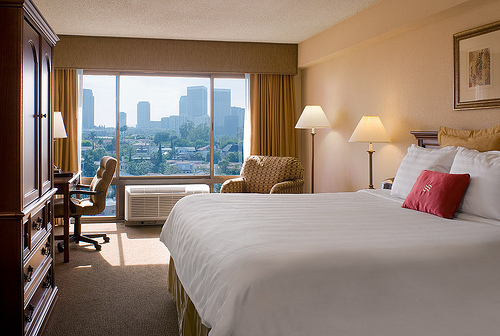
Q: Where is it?
A: This is at the hotel room.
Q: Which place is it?
A: It is a hotel room.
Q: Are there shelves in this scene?
A: No, there are no shelves.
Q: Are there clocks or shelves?
A: No, there are no shelves or clocks.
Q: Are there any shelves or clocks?
A: No, there are no shelves or clocks.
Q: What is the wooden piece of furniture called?
A: The piece of furniture is a dresser.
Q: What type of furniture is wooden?
A: The furniture is a dresser.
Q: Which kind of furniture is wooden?
A: The furniture is a dresser.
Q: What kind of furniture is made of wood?
A: The furniture is a dresser.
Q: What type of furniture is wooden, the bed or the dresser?
A: The dresser is wooden.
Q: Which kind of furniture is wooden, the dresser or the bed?
A: The dresser is wooden.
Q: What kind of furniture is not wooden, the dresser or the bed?
A: The bed is not wooden.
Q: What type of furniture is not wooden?
A: The furniture is a bed.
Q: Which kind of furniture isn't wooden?
A: The furniture is a bed.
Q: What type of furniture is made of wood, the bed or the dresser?
A: The dresser is made of wood.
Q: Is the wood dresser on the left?
A: Yes, the dresser is on the left of the image.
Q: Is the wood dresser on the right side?
A: No, the dresser is on the left of the image.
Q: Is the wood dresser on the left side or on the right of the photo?
A: The dresser is on the left of the image.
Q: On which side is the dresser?
A: The dresser is on the left of the image.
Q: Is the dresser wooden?
A: Yes, the dresser is wooden.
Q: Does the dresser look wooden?
A: Yes, the dresser is wooden.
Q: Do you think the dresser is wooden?
A: Yes, the dresser is wooden.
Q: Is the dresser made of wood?
A: Yes, the dresser is made of wood.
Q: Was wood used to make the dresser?
A: Yes, the dresser is made of wood.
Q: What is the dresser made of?
A: The dresser is made of wood.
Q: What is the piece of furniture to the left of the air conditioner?
A: The piece of furniture is a dresser.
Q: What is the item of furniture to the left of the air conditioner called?
A: The piece of furniture is a dresser.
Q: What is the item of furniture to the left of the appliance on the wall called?
A: The piece of furniture is a dresser.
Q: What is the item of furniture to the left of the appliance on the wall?
A: The piece of furniture is a dresser.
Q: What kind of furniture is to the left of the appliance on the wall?
A: The piece of furniture is a dresser.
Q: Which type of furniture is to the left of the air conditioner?
A: The piece of furniture is a dresser.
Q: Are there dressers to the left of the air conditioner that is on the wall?
A: Yes, there is a dresser to the left of the air conditioner.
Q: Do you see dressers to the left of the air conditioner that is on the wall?
A: Yes, there is a dresser to the left of the air conditioner.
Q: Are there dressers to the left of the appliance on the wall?
A: Yes, there is a dresser to the left of the air conditioner.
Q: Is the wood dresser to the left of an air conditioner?
A: Yes, the dresser is to the left of an air conditioner.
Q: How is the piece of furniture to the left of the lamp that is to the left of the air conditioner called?
A: The piece of furniture is a dresser.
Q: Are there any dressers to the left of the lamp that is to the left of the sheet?
A: Yes, there is a dresser to the left of the lamp.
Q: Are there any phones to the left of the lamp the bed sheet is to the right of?
A: No, there is a dresser to the left of the lamp.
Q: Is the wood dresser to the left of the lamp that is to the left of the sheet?
A: Yes, the dresser is to the left of the lamp.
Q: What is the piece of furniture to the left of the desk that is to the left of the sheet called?
A: The piece of furniture is a dresser.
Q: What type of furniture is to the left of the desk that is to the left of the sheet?
A: The piece of furniture is a dresser.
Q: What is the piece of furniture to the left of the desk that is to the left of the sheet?
A: The piece of furniture is a dresser.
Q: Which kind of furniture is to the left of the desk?
A: The piece of furniture is a dresser.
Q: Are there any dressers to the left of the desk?
A: Yes, there is a dresser to the left of the desk.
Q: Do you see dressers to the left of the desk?
A: Yes, there is a dresser to the left of the desk.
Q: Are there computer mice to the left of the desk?
A: No, there is a dresser to the left of the desk.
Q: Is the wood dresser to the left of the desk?
A: Yes, the dresser is to the left of the desk.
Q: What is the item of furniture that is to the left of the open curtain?
A: The piece of furniture is a dresser.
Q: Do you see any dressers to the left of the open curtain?
A: Yes, there is a dresser to the left of the curtain.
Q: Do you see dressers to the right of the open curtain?
A: No, the dresser is to the left of the curtain.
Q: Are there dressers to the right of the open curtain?
A: No, the dresser is to the left of the curtain.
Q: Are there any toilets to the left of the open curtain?
A: No, there is a dresser to the left of the curtain.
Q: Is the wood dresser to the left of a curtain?
A: Yes, the dresser is to the left of a curtain.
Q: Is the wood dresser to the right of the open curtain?
A: No, the dresser is to the left of the curtain.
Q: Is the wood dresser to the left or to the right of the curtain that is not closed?
A: The dresser is to the left of the curtain.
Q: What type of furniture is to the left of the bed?
A: The piece of furniture is a dresser.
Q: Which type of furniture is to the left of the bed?
A: The piece of furniture is a dresser.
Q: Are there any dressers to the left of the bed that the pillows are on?
A: Yes, there is a dresser to the left of the bed.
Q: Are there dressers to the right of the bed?
A: No, the dresser is to the left of the bed.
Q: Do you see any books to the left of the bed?
A: No, there is a dresser to the left of the bed.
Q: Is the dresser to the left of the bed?
A: Yes, the dresser is to the left of the bed.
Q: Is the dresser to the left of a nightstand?
A: No, the dresser is to the left of the bed.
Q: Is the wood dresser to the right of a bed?
A: No, the dresser is to the left of a bed.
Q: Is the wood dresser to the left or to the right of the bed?
A: The dresser is to the left of the bed.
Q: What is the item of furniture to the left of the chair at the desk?
A: The piece of furniture is a dresser.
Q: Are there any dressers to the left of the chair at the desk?
A: Yes, there is a dresser to the left of the chair.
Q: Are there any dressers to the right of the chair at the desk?
A: No, the dresser is to the left of the chair.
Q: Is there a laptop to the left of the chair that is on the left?
A: No, there is a dresser to the left of the chair.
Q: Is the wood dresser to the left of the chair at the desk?
A: Yes, the dresser is to the left of the chair.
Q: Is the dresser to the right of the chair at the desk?
A: No, the dresser is to the left of the chair.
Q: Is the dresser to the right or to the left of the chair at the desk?
A: The dresser is to the left of the chair.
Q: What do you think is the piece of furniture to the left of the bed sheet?
A: The piece of furniture is a dresser.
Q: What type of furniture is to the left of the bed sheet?
A: The piece of furniture is a dresser.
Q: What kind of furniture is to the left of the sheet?
A: The piece of furniture is a dresser.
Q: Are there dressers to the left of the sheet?
A: Yes, there is a dresser to the left of the sheet.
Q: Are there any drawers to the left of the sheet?
A: No, there is a dresser to the left of the sheet.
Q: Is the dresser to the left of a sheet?
A: Yes, the dresser is to the left of a sheet.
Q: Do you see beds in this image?
A: Yes, there is a bed.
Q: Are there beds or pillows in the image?
A: Yes, there is a bed.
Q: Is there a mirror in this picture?
A: No, there are no mirrors.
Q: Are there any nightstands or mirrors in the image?
A: No, there are no mirrors or nightstands.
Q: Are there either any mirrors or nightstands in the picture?
A: No, there are no mirrors or nightstands.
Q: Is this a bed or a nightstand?
A: This is a bed.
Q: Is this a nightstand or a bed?
A: This is a bed.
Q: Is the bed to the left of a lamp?
A: No, the bed is to the right of a lamp.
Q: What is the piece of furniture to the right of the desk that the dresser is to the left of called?
A: The piece of furniture is a bed.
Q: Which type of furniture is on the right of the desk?
A: The piece of furniture is a bed.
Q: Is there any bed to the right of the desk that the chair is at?
A: Yes, there is a bed to the right of the desk.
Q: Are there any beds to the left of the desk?
A: No, the bed is to the right of the desk.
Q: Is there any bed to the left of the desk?
A: No, the bed is to the right of the desk.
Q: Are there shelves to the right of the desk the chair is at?
A: No, there is a bed to the right of the desk.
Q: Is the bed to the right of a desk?
A: Yes, the bed is to the right of a desk.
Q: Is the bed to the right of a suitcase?
A: No, the bed is to the right of a desk.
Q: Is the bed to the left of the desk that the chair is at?
A: No, the bed is to the right of the desk.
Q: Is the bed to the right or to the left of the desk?
A: The bed is to the right of the desk.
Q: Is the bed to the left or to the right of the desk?
A: The bed is to the right of the desk.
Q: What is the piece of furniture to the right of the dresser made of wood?
A: The piece of furniture is a bed.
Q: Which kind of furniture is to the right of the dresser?
A: The piece of furniture is a bed.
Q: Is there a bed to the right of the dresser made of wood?
A: Yes, there is a bed to the right of the dresser.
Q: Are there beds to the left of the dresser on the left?
A: No, the bed is to the right of the dresser.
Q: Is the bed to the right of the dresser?
A: Yes, the bed is to the right of the dresser.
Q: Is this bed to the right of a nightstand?
A: No, the bed is to the right of the dresser.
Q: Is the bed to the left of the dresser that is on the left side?
A: No, the bed is to the right of the dresser.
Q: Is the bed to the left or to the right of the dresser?
A: The bed is to the right of the dresser.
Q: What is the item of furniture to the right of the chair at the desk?
A: The piece of furniture is a bed.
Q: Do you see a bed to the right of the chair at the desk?
A: Yes, there is a bed to the right of the chair.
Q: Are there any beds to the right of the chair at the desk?
A: Yes, there is a bed to the right of the chair.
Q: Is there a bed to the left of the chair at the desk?
A: No, the bed is to the right of the chair.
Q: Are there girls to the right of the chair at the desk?
A: No, there is a bed to the right of the chair.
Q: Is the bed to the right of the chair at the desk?
A: Yes, the bed is to the right of the chair.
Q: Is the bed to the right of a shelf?
A: No, the bed is to the right of the chair.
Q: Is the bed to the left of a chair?
A: No, the bed is to the right of a chair.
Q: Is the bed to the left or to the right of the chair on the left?
A: The bed is to the right of the chair.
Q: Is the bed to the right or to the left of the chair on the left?
A: The bed is to the right of the chair.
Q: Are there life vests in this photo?
A: No, there are no life vests.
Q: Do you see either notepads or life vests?
A: No, there are no life vests or notepads.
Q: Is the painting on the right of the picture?
A: Yes, the painting is on the right of the image.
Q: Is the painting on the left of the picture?
A: No, the painting is on the right of the image.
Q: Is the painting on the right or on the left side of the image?
A: The painting is on the right of the image.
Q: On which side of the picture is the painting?
A: The painting is on the right of the image.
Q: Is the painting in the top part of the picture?
A: Yes, the painting is in the top of the image.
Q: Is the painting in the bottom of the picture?
A: No, the painting is in the top of the image.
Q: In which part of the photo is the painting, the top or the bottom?
A: The painting is in the top of the image.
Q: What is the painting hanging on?
A: The painting is hanging on the wall.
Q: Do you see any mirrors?
A: No, there are no mirrors.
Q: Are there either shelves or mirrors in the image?
A: No, there are no mirrors or shelves.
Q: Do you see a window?
A: Yes, there is a window.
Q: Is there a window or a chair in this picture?
A: Yes, there is a window.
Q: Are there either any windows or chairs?
A: Yes, there is a window.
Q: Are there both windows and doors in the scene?
A: No, there is a window but no doors.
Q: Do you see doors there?
A: No, there are no doors.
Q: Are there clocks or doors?
A: No, there are no doors or clocks.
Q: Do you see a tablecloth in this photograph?
A: No, there are no tablecloths.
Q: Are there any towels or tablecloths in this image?
A: No, there are no tablecloths or towels.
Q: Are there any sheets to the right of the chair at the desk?
A: Yes, there is a sheet to the right of the chair.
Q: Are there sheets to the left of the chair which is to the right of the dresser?
A: No, the sheet is to the right of the chair.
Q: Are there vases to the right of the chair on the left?
A: No, there is a sheet to the right of the chair.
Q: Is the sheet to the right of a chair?
A: Yes, the sheet is to the right of a chair.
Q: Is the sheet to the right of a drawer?
A: No, the sheet is to the right of a chair.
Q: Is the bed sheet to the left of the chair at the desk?
A: No, the bed sheet is to the right of the chair.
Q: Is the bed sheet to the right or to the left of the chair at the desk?
A: The bed sheet is to the right of the chair.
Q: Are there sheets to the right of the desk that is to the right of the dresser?
A: Yes, there is a sheet to the right of the desk.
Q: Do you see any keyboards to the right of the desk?
A: No, there is a sheet to the right of the desk.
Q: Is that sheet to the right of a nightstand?
A: No, the sheet is to the right of the desk.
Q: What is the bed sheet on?
A: The bed sheet is on the bed.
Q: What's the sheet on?
A: The bed sheet is on the bed.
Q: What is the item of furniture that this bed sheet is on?
A: The piece of furniture is a bed.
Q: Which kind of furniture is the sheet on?
A: The bed sheet is on the bed.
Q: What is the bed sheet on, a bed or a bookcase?
A: The bed sheet is on a bed.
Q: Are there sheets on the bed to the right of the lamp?
A: Yes, there is a sheet on the bed.